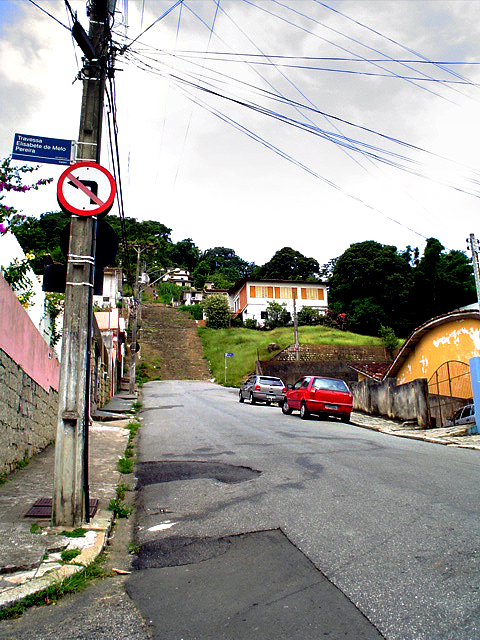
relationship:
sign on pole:
[56, 223, 91, 478] [38, 157, 141, 239]